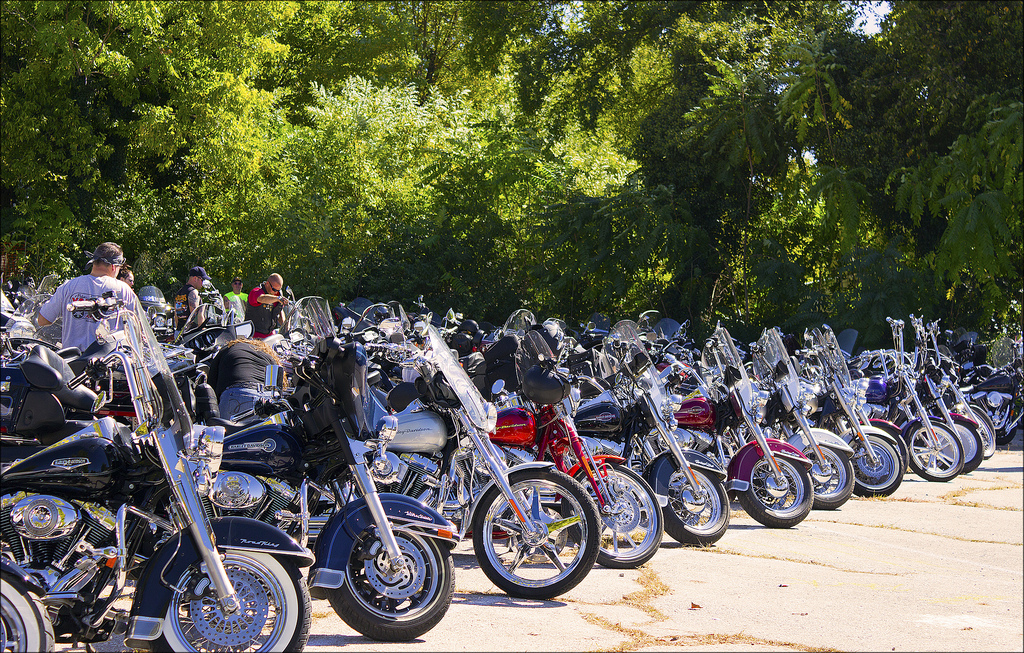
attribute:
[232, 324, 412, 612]
bike — shiny, lined, wheeled, red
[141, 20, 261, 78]
leaves — green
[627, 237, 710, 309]
tree — brown, leafy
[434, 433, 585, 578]
wheel — frront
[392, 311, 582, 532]
motorcycle — two wheeled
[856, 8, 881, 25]
sky — light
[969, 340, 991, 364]
weeds — growing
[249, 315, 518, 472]
motorcycles — roll, parked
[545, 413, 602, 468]
fender — red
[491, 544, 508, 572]
wall — white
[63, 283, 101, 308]
shirt — green, black, gray, red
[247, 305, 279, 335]
vest — black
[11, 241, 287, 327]
people — grouped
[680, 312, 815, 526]
motorcycle — purple